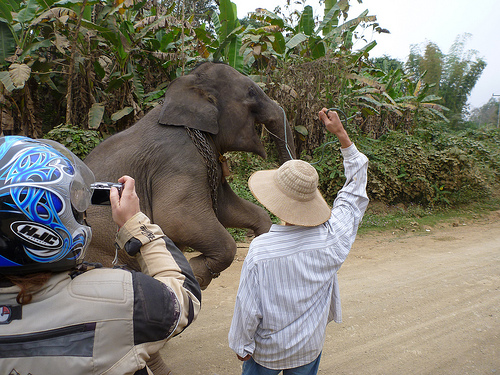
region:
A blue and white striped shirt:
[229, 158, 384, 372]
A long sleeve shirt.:
[229, 143, 370, 373]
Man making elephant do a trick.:
[127, 51, 380, 373]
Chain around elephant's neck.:
[158, 82, 248, 218]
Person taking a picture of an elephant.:
[3, 110, 217, 374]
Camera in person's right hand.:
[81, 167, 169, 249]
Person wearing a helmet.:
[1, 120, 128, 290]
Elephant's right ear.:
[152, 45, 247, 137]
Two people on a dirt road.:
[16, 17, 489, 373]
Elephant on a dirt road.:
[61, 51, 478, 370]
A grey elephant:
[90, 21, 320, 263]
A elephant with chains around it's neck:
[155, 46, 360, 278]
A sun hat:
[240, 143, 337, 236]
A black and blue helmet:
[0, 128, 106, 279]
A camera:
[81, 175, 134, 210]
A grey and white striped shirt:
[227, 141, 394, 373]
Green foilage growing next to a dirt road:
[252, 0, 498, 213]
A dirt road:
[207, 181, 499, 373]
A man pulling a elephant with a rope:
[140, 38, 412, 373]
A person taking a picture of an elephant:
[0, 52, 326, 373]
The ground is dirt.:
[396, 276, 481, 373]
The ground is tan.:
[392, 255, 499, 372]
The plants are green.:
[12, 9, 154, 101]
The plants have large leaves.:
[11, 1, 131, 91]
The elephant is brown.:
[75, 53, 296, 240]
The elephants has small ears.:
[152, 73, 227, 138]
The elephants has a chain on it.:
[162, 103, 232, 219]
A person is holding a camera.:
[68, 167, 149, 218]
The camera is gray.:
[81, 173, 131, 210]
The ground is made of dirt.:
[400, 279, 490, 372]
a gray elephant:
[44, 57, 303, 318]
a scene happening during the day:
[17, 11, 494, 341]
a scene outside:
[17, 16, 479, 373]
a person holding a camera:
[5, 136, 205, 372]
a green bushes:
[4, 7, 498, 221]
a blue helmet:
[0, 130, 105, 285]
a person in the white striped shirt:
[210, 227, 367, 372]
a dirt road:
[16, 211, 498, 370]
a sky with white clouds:
[236, 3, 498, 79]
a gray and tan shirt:
[0, 238, 213, 373]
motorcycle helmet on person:
[0, 125, 134, 267]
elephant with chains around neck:
[68, 56, 308, 300]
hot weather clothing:
[250, 81, 397, 371]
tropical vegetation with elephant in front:
[207, 16, 483, 187]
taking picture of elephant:
[4, 143, 203, 350]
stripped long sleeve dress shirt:
[235, 214, 380, 374]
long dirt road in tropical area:
[350, 153, 494, 322]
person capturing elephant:
[137, 51, 403, 239]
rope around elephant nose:
[220, 81, 370, 198]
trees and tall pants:
[14, 9, 142, 124]